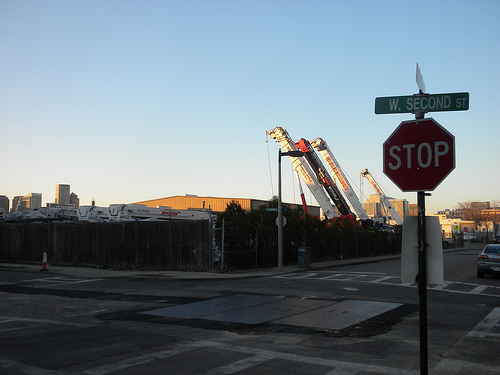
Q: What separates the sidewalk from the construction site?
A: Brown security fence.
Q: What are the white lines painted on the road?
A: Crosswalk for pedestrians.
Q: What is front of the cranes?
A: A light pole.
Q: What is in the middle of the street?
A: Fresh concrete.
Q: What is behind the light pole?
A: Cranes.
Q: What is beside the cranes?
A: A building.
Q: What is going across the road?
A: A cross walk.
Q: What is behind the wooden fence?
A: Cranes.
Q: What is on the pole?
A: A sign.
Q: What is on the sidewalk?
A: A light pole.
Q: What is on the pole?
A: A stop sign and street signs.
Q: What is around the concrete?
A: Black top.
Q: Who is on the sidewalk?
A: Unoccupied.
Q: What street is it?
A: W. Second St.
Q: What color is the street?
A: Black.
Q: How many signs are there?
A: Three.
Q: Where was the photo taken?
A: On the street.